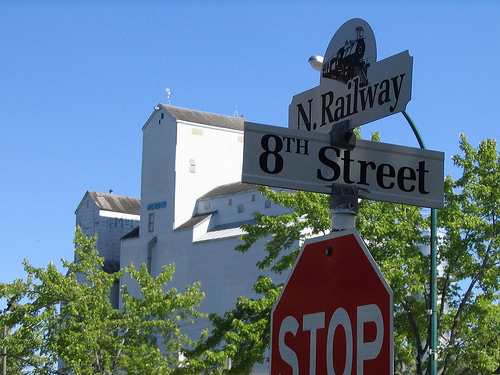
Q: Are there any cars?
A: No, there are no cars.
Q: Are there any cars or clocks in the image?
A: No, there are no cars or clocks.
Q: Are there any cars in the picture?
A: No, there are no cars.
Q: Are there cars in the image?
A: No, there are no cars.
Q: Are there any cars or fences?
A: No, there are no cars or fences.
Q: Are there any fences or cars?
A: No, there are no cars or fences.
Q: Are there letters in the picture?
A: Yes, there are letters.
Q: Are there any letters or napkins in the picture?
A: Yes, there are letters.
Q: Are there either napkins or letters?
A: Yes, there are letters.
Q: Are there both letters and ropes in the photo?
A: No, there are letters but no ropes.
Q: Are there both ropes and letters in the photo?
A: No, there are letters but no ropes.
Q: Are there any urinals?
A: No, there are no urinals.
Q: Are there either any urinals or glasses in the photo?
A: No, there are no urinals or glasses.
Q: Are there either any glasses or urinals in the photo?
A: No, there are no urinals or glasses.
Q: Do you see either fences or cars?
A: No, there are no cars or fences.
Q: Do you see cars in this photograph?
A: No, there are no cars.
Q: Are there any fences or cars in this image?
A: No, there are no cars or fences.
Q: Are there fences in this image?
A: No, there are no fences.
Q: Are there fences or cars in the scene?
A: No, there are no fences or cars.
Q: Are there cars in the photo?
A: No, there are no cars.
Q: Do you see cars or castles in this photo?
A: No, there are no cars or castles.